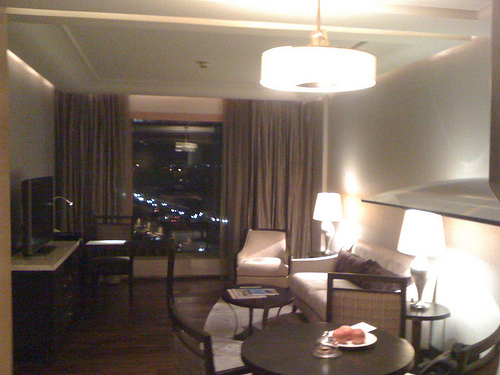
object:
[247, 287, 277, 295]
books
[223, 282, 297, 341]
table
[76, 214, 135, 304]
chair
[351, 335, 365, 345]
food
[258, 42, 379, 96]
chandelier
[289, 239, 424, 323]
couch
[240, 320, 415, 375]
table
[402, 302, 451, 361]
table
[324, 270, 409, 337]
chair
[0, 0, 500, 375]
hotel room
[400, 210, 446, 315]
lamp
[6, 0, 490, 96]
ceiling